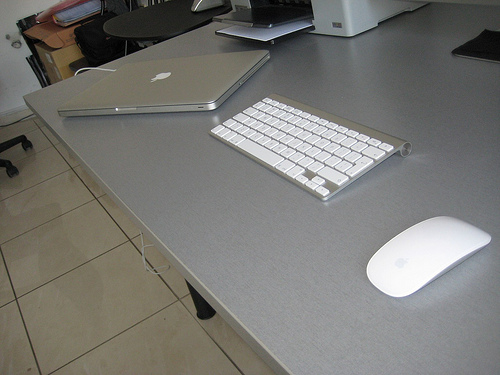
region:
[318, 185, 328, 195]
a key on a keyboard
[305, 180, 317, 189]
a key on a keyboard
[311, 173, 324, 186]
a key on a keyboard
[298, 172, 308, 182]
a key on a keyboard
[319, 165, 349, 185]
a key on a keyboard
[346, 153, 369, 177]
a key on a keyboard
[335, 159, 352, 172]
a key on a keyboard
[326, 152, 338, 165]
a key on a keyboard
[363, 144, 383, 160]
a key on a keyboard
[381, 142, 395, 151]
a key on a keyboard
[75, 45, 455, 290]
One laptop is in table.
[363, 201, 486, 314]
Mouse is white color.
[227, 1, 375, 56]
Printer is in the table.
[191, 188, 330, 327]
Table is grey color.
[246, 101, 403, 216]
Keyboard is white and grey color.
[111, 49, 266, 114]
Laptop brand is Apple.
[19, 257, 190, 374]
Floor is made of tiles.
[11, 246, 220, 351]
Tiles is white color.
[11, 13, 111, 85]
Box is brown color.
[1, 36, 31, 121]
Wall is white color.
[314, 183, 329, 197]
a key on a keyboard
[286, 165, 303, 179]
a key on a keyboard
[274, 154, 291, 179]
a key on a keyboard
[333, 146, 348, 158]
a key on a keyboard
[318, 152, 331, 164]
a key on a keyboard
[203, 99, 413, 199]
A COMPUTER KEYBOARD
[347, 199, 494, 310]
A WHITE APPLE MOUSE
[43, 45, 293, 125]
A SILVER APPLE LAPTOP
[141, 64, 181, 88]
THE APPLE LOGO ON A LAPTOP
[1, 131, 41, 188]
TWO BLACK WHEELS OF A CHAIR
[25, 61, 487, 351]
A METAL TABLE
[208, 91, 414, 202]
WHITE KEYS OF A KEYBOARD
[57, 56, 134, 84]
A LAPTOP CORD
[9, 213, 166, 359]
A TAN TILE FLOOR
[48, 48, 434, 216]
A LAPTOP AND KEYBOARD ON A DESK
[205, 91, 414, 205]
The white and silver keyboard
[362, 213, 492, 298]
The white mouse on the desk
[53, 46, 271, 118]
The silver apple laptop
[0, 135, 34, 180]
The showing part of the rolling chair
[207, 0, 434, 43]
The white printer with paper in ite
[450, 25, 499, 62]
The black keyboard on the desk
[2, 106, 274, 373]
The tiles on the floor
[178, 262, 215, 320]
The black leg of the desk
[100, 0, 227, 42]
The round black table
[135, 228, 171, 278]
The white wire on the ground